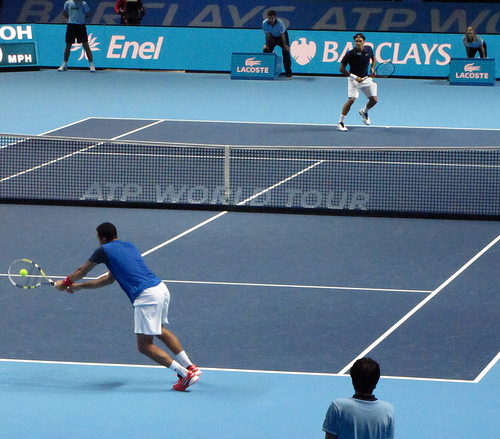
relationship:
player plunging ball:
[54, 221, 200, 394] [13, 259, 37, 281]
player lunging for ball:
[54, 221, 200, 394] [19, 267, 27, 277]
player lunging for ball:
[54, 221, 200, 394] [18, 267, 28, 276]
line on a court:
[327, 233, 497, 377] [4, 68, 496, 433]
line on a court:
[1, 357, 472, 386] [4, 68, 496, 433]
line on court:
[1, 357, 472, 386] [13, 110, 499, 391]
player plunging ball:
[70, 237, 182, 387] [11, 250, 34, 295]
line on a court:
[1, 343, 477, 395] [4, 68, 496, 433]